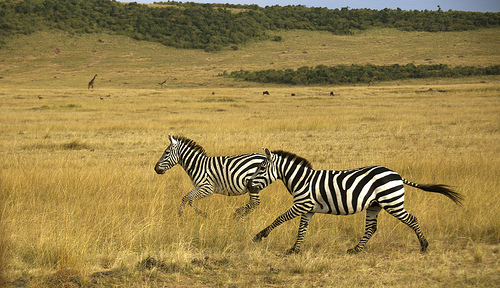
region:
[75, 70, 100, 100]
Giraffe in the background.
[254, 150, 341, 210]
Zebra running in front of the camera.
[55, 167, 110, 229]
Dry grass where the zebras are running.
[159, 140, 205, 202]
Other zebra running next to the first.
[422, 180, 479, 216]
Tail of the zebra.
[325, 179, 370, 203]
Markings of the zebra.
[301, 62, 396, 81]
Bushes in the background.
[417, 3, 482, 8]
Light blue sky at the top of the picture.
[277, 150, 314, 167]
Mane of the zebra.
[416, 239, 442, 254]
Hoof of the zebra.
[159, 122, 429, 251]
two black and white zebras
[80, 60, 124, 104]
large giraffe in distance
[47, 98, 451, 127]
large grassy field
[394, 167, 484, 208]
black puffy zebra tail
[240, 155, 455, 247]
right black and white zebra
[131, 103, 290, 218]
left black and white zebra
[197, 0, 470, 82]
large green grassy area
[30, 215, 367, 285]
tall tan hay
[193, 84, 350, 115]
small fielded animals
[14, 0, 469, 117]
large hill behind animals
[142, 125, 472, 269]
two zebras running through the tall dried grass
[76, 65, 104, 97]
a giraffe in the distance quite far away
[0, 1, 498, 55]
green trees growing on the hill in the distance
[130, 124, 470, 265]
each zebra has a different stripe pattern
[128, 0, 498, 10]
a small slit of blue sky is visible in the distance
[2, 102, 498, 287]
the grass is yellowed due to lack of rain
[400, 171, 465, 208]
the zebra's tall has long hair at the tip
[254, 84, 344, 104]
large animals in the distance grazing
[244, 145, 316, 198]
the zebra has a short mane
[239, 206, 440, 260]
the zebra's legs has stripes that are very close together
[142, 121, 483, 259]
Zebras running in the meadow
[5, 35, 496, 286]
Field has dry grass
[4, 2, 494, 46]
Green brushes in the ground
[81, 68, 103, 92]
A giraffe on back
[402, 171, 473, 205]
Tail of giraffe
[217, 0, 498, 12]
Sky is blue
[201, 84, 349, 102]
Animals pasting in the meadow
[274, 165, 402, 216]
Stripes of zebra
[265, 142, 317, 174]
Dark mane of zebra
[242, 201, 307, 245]
Left leg stepping forward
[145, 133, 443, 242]
two zebras are walking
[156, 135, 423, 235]
they are black and white in color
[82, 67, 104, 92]
the giraffe is far away from the zebras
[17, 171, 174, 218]
the grass are tall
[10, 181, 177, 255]
the grass are brown in color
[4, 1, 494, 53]
trees are on the farthest part of the photo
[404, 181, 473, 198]
the zebras tail is on the air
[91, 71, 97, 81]
the giraffe has tail neck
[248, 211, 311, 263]
the zebras legs are far apart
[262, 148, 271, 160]
the zebra has long ears